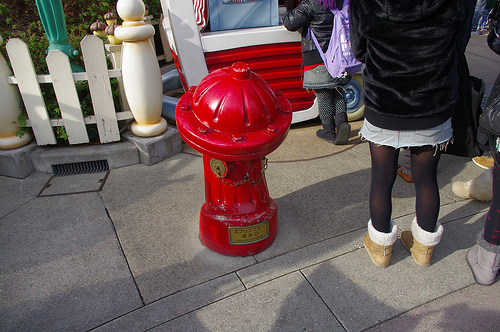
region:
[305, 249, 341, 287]
part of a walkpath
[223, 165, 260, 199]
part of a chain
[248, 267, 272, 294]
part of a line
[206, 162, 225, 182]
part of a bolt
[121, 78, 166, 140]
part of a tank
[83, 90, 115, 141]
part of a wood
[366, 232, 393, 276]
part of a shoe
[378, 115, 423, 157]
part of a skirt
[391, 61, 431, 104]
part of a jumper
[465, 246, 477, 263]
edge of a shoe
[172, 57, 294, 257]
red fire hydrant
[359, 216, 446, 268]
pair of tan boots with fleece lining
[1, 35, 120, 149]
white picket fence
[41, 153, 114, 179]
metal grate in curb of sidewalk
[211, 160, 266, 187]
metal chain on fire hydrant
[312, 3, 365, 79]
purple backpack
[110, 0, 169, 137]
white picket fence pole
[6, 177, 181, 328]
grey cement sidewalk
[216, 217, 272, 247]
gold metal sign plate on fire hydrant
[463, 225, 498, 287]
grey boot with dark grey fleece lining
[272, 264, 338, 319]
part of a floor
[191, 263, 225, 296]
part of a line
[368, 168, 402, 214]
part of a stocking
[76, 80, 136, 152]
part of a board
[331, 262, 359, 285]
edge of a shadow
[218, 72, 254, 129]
top of a tank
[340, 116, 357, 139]
sole of a shoe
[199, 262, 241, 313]
part of a shade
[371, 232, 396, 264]
part of some shoe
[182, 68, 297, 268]
red shiny fire hydrant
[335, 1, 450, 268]
girl standing on street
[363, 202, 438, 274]
girl wearing tan uggs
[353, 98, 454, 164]
girl wearing jean skirt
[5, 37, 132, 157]
white picket fence on side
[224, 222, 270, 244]
gold plaque on fire hydrant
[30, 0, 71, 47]
green pole inside fence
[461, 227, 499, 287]
grey uggs on person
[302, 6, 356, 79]
purple backpack on person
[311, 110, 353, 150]
person wearing black uggs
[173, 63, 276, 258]
a red fire hydrant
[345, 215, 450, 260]
boots on a woman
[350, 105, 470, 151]
a short skirt on a woman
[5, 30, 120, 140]
a white fence next to a walkway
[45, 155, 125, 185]
a drain on the walkway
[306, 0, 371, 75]
a purple backpack on a woman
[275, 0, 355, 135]
a woman in a black jacket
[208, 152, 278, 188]
a chain on a fire hydrant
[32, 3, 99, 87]
a green post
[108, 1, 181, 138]
a fat white fence post